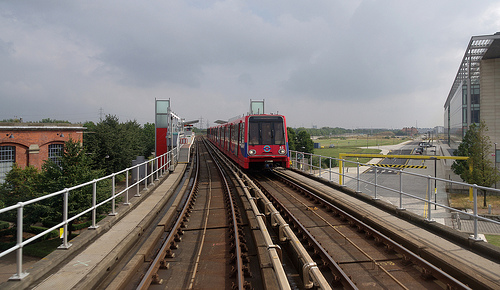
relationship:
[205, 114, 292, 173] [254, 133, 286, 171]
train with spots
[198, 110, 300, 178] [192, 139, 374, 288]
train on tracks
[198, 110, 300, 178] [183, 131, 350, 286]
train on track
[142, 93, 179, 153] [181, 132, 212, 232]
platform on trackside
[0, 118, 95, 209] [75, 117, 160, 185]
building in trees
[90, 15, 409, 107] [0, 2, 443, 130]
clouds in sky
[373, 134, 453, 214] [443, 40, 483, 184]
highway in front of building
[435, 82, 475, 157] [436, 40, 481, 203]
glass fronted building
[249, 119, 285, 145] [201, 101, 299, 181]
windshield on train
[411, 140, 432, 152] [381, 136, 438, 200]
cars on street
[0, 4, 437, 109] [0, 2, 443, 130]
clouds in sky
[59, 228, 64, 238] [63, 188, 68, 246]
sign on a post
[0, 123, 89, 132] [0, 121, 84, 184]
roof on a building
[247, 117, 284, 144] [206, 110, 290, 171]
window on a train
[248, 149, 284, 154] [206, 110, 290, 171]
lights on a train